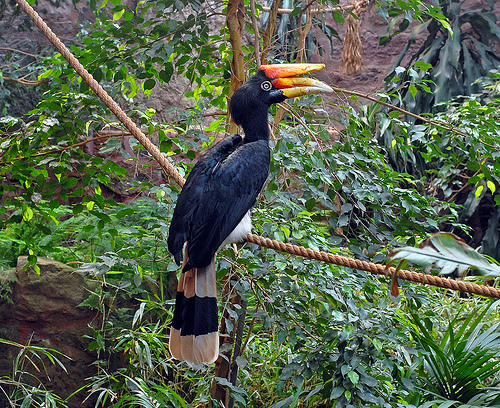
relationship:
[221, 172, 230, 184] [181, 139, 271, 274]
feather on wing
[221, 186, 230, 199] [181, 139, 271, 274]
feather on wing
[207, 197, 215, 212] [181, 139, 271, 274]
feather on wing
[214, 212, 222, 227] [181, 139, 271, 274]
feather on wing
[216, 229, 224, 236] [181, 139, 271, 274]
feather on wing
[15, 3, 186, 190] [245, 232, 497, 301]
rope hanging from rope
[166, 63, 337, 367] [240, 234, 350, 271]
bird on rope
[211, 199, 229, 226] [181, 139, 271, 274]
black feathers on wing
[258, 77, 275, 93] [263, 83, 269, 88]
ring on eye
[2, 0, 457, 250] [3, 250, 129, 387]
dirt on rock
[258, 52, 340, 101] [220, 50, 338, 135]
beak on head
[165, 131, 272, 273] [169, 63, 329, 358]
wings close to bird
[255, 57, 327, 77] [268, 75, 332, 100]
appendage over beak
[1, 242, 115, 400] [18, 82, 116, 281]
rock surrended by leaves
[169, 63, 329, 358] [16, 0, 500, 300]
bird on rope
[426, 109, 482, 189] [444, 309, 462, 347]
plant and leaf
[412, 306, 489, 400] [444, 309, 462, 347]
plant and leaf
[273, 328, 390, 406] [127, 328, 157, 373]
plant and leaf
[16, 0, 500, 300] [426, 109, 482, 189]
rope and plant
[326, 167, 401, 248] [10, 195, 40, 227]
plant and leaf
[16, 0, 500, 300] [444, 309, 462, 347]
rope and leaf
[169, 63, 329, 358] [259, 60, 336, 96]
bird with a beak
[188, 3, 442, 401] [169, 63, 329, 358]
tree on side of bird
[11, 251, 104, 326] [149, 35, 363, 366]
rock on other side of bird